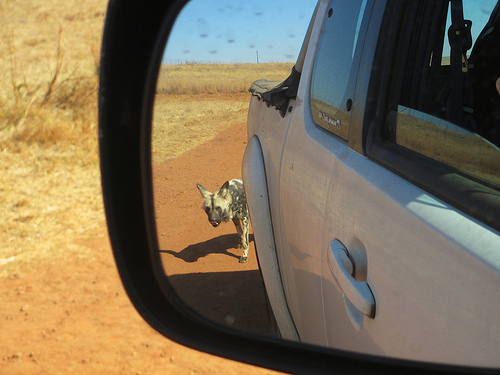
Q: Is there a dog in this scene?
A: Yes, there is a dog.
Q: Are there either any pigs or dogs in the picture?
A: Yes, there is a dog.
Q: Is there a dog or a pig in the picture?
A: Yes, there is a dog.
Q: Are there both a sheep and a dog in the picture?
A: No, there is a dog but no sheep.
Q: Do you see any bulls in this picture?
A: No, there are no bulls.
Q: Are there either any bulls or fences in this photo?
A: No, there are no bulls or fences.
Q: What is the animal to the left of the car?
A: The animal is a dog.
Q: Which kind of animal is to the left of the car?
A: The animal is a dog.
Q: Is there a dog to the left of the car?
A: Yes, there is a dog to the left of the car.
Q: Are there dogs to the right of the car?
A: No, the dog is to the left of the car.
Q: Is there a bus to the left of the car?
A: No, there is a dog to the left of the car.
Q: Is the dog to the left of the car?
A: Yes, the dog is to the left of the car.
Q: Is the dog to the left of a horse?
A: No, the dog is to the left of the car.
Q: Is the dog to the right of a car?
A: No, the dog is to the left of a car.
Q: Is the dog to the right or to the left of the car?
A: The dog is to the left of the car.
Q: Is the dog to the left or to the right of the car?
A: The dog is to the left of the car.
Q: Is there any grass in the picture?
A: Yes, there is grass.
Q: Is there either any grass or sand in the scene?
A: Yes, there is grass.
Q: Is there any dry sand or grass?
A: Yes, there is dry grass.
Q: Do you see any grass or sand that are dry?
A: Yes, the grass is dry.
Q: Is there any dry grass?
A: Yes, there is dry grass.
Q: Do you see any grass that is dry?
A: Yes, there is grass that is dry.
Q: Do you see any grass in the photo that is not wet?
A: Yes, there is dry grass.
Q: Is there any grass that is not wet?
A: Yes, there is dry grass.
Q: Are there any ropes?
A: No, there are no ropes.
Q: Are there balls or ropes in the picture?
A: No, there are no ropes or balls.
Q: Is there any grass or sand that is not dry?
A: No, there is grass but it is dry.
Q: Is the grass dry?
A: Yes, the grass is dry.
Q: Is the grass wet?
A: No, the grass is dry.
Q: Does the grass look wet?
A: No, the grass is dry.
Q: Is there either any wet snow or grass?
A: No, there is grass but it is dry.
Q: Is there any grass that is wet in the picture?
A: No, there is grass but it is dry.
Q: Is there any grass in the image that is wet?
A: No, there is grass but it is dry.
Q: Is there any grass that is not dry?
A: No, there is grass but it is dry.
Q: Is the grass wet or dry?
A: The grass is dry.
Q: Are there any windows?
A: Yes, there is a window.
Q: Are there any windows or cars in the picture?
A: Yes, there is a window.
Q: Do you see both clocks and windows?
A: No, there is a window but no clocks.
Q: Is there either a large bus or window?
A: Yes, there is a large window.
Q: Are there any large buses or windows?
A: Yes, there is a large window.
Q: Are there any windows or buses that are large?
A: Yes, the window is large.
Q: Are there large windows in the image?
A: Yes, there is a large window.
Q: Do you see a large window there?
A: Yes, there is a large window.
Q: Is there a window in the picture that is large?
A: Yes, there is a window that is large.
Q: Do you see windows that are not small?
A: Yes, there is a large window.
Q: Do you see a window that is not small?
A: Yes, there is a large window.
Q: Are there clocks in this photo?
A: No, there are no clocks.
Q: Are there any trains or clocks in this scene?
A: No, there are no clocks or trains.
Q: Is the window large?
A: Yes, the window is large.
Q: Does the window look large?
A: Yes, the window is large.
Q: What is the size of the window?
A: The window is large.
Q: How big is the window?
A: The window is large.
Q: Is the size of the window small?
A: No, the window is large.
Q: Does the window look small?
A: No, the window is large.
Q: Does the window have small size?
A: No, the window is large.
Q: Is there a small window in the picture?
A: No, there is a window but it is large.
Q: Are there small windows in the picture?
A: No, there is a window but it is large.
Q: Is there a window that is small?
A: No, there is a window but it is large.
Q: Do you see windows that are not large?
A: No, there is a window but it is large.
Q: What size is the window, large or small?
A: The window is large.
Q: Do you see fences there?
A: No, there are no fences.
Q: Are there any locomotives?
A: No, there are no locomotives.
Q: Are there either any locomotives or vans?
A: No, there are no locomotives or vans.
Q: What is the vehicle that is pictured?
A: The vehicle is a car.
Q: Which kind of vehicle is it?
A: The vehicle is a car.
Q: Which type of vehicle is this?
A: This is a car.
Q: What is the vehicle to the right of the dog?
A: The vehicle is a car.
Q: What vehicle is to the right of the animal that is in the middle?
A: The vehicle is a car.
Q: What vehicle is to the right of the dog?
A: The vehicle is a car.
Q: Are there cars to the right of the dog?
A: Yes, there is a car to the right of the dog.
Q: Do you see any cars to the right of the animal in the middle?
A: Yes, there is a car to the right of the dog.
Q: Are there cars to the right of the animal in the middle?
A: Yes, there is a car to the right of the dog.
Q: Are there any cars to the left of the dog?
A: No, the car is to the right of the dog.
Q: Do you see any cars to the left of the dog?
A: No, the car is to the right of the dog.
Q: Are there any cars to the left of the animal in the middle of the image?
A: No, the car is to the right of the dog.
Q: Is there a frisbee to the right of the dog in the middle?
A: No, there is a car to the right of the dog.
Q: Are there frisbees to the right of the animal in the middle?
A: No, there is a car to the right of the dog.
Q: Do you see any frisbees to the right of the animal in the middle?
A: No, there is a car to the right of the dog.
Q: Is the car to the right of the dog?
A: Yes, the car is to the right of the dog.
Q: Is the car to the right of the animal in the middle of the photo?
A: Yes, the car is to the right of the dog.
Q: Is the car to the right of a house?
A: No, the car is to the right of the dog.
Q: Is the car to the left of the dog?
A: No, the car is to the right of the dog.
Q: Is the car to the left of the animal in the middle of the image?
A: No, the car is to the right of the dog.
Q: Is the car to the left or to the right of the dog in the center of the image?
A: The car is to the right of the dog.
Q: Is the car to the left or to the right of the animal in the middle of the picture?
A: The car is to the right of the dog.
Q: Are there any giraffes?
A: No, there are no giraffes.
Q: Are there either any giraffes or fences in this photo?
A: No, there are no giraffes or fences.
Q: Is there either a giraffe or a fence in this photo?
A: No, there are no giraffes or fences.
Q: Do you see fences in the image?
A: No, there are no fences.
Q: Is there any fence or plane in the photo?
A: No, there are no fences or airplanes.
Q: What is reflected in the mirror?
A: The sky is reflected in the mirror.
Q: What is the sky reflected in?
A: The sky is reflected in the mirror.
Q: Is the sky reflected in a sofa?
A: No, the sky is reflected in the mirror.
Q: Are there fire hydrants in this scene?
A: No, there are no fire hydrants.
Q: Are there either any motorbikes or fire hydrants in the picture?
A: No, there are no fire hydrants or motorbikes.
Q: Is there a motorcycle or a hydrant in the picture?
A: No, there are no fire hydrants or motorcycles.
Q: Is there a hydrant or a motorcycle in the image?
A: No, there are no fire hydrants or motorcycles.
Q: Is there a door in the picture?
A: Yes, there is a door.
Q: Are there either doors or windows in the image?
A: Yes, there is a door.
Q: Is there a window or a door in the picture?
A: Yes, there is a door.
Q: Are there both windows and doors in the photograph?
A: Yes, there are both a door and a window.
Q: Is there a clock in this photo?
A: No, there are no clocks.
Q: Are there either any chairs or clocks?
A: No, there are no clocks or chairs.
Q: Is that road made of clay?
A: Yes, the road is made of clay.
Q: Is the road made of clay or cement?
A: The road is made of clay.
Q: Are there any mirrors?
A: Yes, there is a mirror.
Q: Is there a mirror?
A: Yes, there is a mirror.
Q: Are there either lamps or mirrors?
A: Yes, there is a mirror.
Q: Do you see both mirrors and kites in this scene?
A: No, there is a mirror but no kites.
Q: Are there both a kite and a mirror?
A: No, there is a mirror but no kites.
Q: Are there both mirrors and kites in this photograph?
A: No, there is a mirror but no kites.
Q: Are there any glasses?
A: No, there are no glasses.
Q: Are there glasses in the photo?
A: No, there are no glasses.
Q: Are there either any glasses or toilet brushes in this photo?
A: No, there are no glasses or toilet brushes.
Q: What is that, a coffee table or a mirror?
A: That is a mirror.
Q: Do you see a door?
A: Yes, there is a door.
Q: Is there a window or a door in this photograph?
A: Yes, there is a door.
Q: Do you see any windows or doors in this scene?
A: Yes, there is a door.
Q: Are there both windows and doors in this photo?
A: Yes, there are both a door and a window.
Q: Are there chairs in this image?
A: No, there are no chairs.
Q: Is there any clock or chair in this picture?
A: No, there are no chairs or clocks.